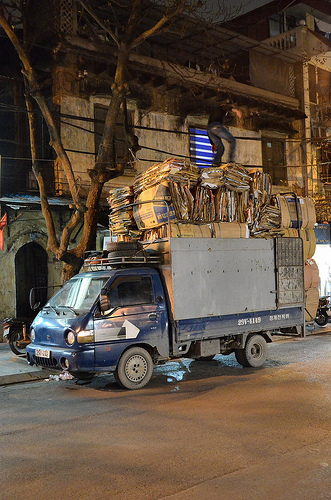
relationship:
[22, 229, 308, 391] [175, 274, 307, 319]
pick up with truck bed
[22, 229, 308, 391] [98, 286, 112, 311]
pick up has mirror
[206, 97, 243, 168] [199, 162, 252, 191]
man standing on boxes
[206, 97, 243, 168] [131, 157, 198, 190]
man standing on boxes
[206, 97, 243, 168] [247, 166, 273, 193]
man standing on boxes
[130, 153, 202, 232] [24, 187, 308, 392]
carton on pick up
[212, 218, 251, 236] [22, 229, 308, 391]
carton on pick up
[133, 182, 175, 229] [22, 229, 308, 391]
card board on pick up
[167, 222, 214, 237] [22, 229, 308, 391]
carton on pick up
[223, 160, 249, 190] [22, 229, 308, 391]
carton on pick up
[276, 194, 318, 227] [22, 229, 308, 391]
carton on pick up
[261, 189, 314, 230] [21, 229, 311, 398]
carton on pickup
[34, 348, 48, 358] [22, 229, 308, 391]
license plate on pick up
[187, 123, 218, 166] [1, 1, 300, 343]
window on building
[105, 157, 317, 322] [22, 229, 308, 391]
card board inside pick up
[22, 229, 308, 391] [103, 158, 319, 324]
pick up has compacted boxes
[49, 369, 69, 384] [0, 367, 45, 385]
litter on curb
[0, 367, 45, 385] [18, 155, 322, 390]
curb next to truck